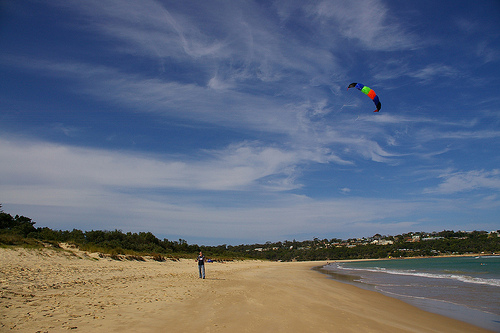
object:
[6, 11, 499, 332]
air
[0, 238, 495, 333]
beach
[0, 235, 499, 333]
sand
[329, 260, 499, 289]
wave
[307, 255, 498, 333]
shore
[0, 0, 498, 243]
clouds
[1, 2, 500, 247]
sky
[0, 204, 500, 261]
trees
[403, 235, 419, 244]
houses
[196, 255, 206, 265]
shirt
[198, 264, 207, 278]
jeans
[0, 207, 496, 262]
greenery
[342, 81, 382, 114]
kite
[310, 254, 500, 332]
water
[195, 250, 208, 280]
man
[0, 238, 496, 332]
land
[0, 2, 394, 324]
side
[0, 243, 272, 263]
area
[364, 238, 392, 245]
building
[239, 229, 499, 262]
hills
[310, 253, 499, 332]
edge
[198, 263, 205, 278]
trouser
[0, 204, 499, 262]
forest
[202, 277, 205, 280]
shoes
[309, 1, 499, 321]
right